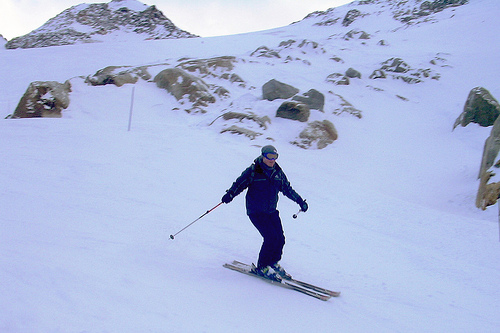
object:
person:
[221, 144, 308, 282]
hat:
[261, 144, 277, 155]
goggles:
[262, 150, 279, 159]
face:
[263, 151, 279, 166]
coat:
[228, 156, 302, 214]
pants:
[247, 208, 285, 268]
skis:
[223, 260, 341, 300]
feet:
[251, 262, 291, 282]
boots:
[247, 264, 284, 282]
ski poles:
[168, 198, 231, 242]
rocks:
[450, 85, 500, 208]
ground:
[0, 0, 498, 332]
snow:
[0, 0, 499, 333]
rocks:
[0, 1, 221, 51]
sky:
[0, 1, 353, 40]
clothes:
[222, 159, 302, 267]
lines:
[0, 131, 498, 332]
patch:
[251, 162, 264, 178]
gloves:
[220, 190, 237, 206]